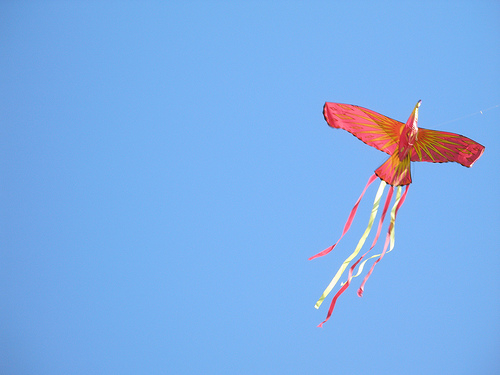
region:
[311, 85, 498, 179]
large red kite in air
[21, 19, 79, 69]
blue sky with no clouds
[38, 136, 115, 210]
blue sky with no clouds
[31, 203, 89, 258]
blue sky with no clouds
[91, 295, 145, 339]
blue sky with no clouds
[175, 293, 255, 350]
blue sky with no clouds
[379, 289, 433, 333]
blue sky with no clouds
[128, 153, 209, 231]
blue sky with no clouds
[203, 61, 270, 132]
blue sky with no clouds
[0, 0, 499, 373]
a clear blue sky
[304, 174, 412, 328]
red ribbons on kite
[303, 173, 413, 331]
yellow ribbons on kite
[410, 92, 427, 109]
point of kite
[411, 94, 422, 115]
yellow end of kite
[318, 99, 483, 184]
the firey of kite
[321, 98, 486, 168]
wings in flight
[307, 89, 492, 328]
kite going upward motion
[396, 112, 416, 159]
body of the bird kite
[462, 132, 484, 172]
one wing bent at end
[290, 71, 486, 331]
red and yellow bird kite in the sky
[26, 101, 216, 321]
crystal clear blue sky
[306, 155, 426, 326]
tail of a red and yellow kite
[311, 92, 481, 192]
winds of a red and yellow bird kite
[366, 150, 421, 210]
tail of a bird kite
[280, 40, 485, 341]
kite flying in a clear blue sky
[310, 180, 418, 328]
streamers on the end of a kite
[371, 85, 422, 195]
body of a bird kite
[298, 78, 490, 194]
red kite with yellow design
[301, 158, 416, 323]
red and yellow ribbons on a bird kite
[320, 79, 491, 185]
red bird kite in the sky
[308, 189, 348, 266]
red string on the kite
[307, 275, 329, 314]
yellow string on the kite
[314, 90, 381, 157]
wing of the kite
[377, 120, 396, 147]
yellow on the kite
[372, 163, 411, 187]
tail of the bird kite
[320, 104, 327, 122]
black on the tip of the kite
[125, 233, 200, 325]
clear blue sunny sky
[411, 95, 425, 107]
tip of the bird kite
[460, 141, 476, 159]
red design on the kite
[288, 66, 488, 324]
kite flying that looks like bird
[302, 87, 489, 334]
pink and yellow bird shaped kite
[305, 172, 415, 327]
white and pink streamers on kite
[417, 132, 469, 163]
orange, yellow, and pink design on wings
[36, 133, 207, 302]
clear blue sky with no clouds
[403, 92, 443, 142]
yellow face of bird shaped kite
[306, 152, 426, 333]
tail of kite with streamers in pink and white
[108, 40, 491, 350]
kite flying in clear blue sky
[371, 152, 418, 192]
pink tail with yellow and orange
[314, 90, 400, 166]
light coming through wing of sheer kite fabric